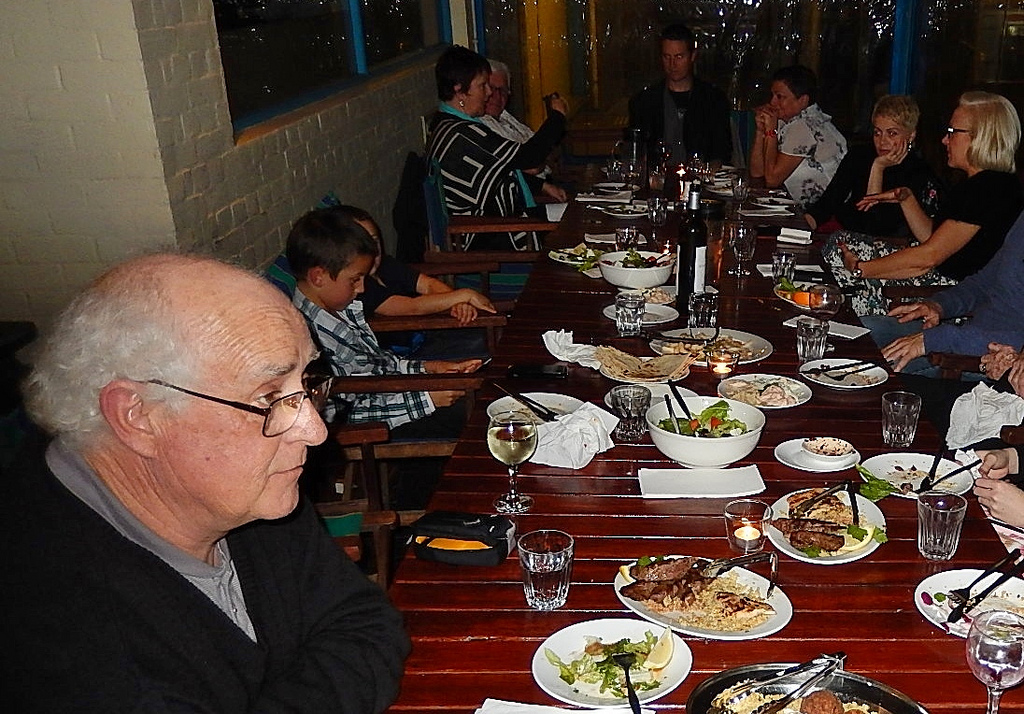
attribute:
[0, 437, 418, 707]
jacket — black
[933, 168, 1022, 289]
shirt — black, short sleeve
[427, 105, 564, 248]
shirt — white, black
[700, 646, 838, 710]
tongs — silver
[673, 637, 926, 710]
platter — silver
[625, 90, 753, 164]
coat — sport coat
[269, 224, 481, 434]
boy — young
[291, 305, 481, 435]
shirt — plaid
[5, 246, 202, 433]
hair — gray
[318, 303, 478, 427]
shirt — plaid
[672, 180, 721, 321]
bottle — wine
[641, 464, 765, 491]
napkin — white 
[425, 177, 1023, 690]
table — wood, slatted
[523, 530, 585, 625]
glass — half full, half empty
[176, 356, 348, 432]
eyeglasses — black, metal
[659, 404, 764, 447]
salad — family style, lettuce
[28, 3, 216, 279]
blocks — painted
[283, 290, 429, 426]
jacket — grey, plaid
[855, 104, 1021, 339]
woman — blond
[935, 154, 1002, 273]
shirt — black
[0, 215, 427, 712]
man — bald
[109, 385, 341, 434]
glasses — old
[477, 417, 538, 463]
wine — white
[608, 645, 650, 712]
silverware — dirty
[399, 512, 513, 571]
camera case — black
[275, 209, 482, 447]
child — male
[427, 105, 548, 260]
shirt — black, white, patterened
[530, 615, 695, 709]
plate — white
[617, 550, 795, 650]
plate — white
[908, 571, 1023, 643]
plate — white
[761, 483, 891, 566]
plate — white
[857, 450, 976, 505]
plate — white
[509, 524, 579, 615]
glass — small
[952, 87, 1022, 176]
hair — blonde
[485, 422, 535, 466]
wine — white wine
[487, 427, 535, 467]
wine — white wine